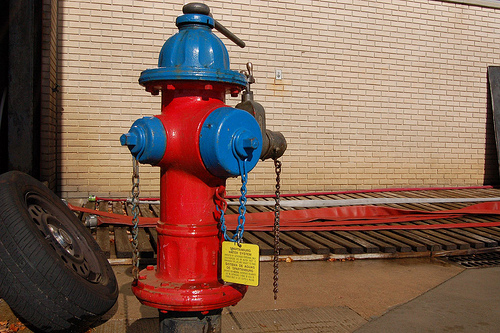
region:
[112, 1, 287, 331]
a fire hydrant is in front of a building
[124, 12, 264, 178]
the top and the plugs of the hydrant are blue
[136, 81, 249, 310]
the body of the hydrant is red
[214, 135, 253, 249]
a blue chain is hanging from the plug cap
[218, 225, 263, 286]
a yellow tag is on a blue chain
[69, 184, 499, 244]
fire hoses are laid out on the pallet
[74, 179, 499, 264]
the fire hoses are red and gray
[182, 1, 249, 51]
a wrench is on top of the hydrant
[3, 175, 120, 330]
a tire is laying against a wall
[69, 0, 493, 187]
the wall behind the hydrant is white brick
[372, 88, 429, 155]
part of a wall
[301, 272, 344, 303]
part of a floor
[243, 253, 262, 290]
edge of a card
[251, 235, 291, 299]
part of a chain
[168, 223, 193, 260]
part of a tank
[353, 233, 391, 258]
part of a stair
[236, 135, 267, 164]
part of a bolt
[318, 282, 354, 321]
part of a floor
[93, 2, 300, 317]
A blue, red and gray fire hydrant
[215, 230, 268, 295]
A yellow tag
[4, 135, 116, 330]
A black tire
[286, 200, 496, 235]
Red fire hose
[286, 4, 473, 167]
Beige brick wall on a building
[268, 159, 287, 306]
A gray chain on a fire hydrant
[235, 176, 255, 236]
A blue chain on a fire hydrant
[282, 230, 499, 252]
Brown wooden planks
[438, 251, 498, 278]
A gray sewer grate cover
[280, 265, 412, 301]
Brown concrete surface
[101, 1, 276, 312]
this is a hydrant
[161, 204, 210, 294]
it is red in color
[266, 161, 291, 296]
this is a chain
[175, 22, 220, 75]
the id is blue in color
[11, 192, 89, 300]
this is a wheel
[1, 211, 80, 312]
the whee is black in color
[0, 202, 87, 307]
the whee is slanted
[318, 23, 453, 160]
this is a wall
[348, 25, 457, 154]
the wall is made of bricks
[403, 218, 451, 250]
these are wood arranged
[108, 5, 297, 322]
The fire hydrant is blue and red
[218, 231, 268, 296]
A yellow sign is on the blue chain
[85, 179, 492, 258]
A wooden pellet is on the ground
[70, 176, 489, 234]
Red and grey hoses lie on top of the pellet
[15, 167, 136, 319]
A spare tire rests on its side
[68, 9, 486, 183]
Large white brick wall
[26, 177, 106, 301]
The middle of the tire is silver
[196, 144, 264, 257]
The chain attached to the hydrant is blue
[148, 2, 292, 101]
There is a silver attached to the top of the hydrant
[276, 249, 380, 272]
There are brown leaves on the ground